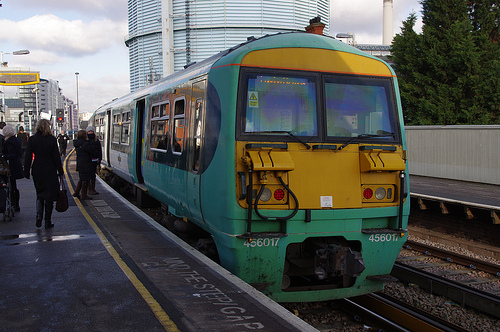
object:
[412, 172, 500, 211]
ground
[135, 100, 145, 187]
door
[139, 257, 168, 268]
markings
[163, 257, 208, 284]
incorrect sentence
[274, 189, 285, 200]
headlights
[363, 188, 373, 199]
headlights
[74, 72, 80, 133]
lamp post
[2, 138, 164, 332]
street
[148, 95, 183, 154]
windows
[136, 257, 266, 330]
paint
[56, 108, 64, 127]
signal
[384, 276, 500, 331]
stone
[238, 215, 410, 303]
bumper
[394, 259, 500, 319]
plumbing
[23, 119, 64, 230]
people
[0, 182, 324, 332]
platform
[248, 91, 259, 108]
sticker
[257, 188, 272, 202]
headlight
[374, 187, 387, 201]
headlight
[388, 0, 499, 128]
tree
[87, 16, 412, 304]
train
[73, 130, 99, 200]
person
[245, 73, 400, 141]
glass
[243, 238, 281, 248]
numbers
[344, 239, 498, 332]
train tracks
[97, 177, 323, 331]
white line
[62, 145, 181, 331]
line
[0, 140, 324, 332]
sidewalk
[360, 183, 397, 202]
head light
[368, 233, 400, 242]
number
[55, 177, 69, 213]
bag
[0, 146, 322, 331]
ground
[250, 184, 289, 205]
light